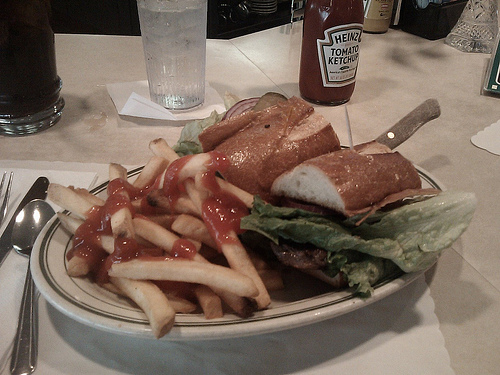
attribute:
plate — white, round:
[19, 134, 454, 338]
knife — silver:
[0, 173, 55, 259]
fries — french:
[25, 140, 290, 337]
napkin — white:
[106, 75, 226, 121]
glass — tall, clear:
[136, 0, 208, 112]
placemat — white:
[5, 175, 414, 373]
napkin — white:
[3, 158, 458, 373]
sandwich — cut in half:
[237, 87, 424, 254]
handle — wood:
[380, 99, 440, 144]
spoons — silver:
[8, 178, 83, 371]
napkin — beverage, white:
[107, 73, 234, 131]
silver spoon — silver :
[20, 197, 67, 373]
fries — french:
[102, 181, 214, 302]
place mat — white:
[2, 151, 453, 374]